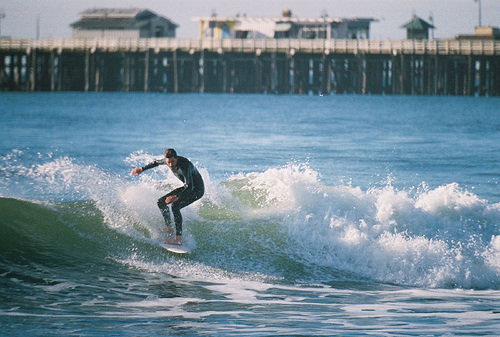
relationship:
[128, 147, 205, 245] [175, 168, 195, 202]
man has arm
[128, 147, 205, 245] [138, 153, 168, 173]
man has arm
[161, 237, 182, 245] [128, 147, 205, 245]
feet of man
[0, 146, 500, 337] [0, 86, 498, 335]
wave crashing in water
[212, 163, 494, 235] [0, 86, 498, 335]
wave crashing in water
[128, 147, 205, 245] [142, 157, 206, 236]
man surfing in wet suit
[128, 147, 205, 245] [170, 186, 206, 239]
man has leg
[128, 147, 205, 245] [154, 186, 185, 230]
man has person's leg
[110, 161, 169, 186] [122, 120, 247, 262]
hand of a person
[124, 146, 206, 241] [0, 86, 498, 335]
man surfing on water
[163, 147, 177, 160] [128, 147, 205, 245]
hair on man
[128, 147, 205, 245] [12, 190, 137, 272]
man riding wave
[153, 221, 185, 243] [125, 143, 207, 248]
feet of surfers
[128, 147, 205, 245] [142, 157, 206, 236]
man wearing wet suit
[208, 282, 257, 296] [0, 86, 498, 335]
foam in water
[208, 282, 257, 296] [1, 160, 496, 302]
foam from waves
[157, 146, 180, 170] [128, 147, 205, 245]
head on man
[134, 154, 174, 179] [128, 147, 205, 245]
arm of man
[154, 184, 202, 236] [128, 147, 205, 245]
leg of a man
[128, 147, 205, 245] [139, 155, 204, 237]
man wearing a wet suit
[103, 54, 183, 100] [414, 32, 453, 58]
houses near pier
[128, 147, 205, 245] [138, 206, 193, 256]
man on a surfboard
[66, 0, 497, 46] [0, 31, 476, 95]
buildings on boardwalk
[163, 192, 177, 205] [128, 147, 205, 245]
hand of man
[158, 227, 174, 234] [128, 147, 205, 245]
foot of man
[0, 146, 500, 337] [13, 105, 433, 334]
wave crashing in water